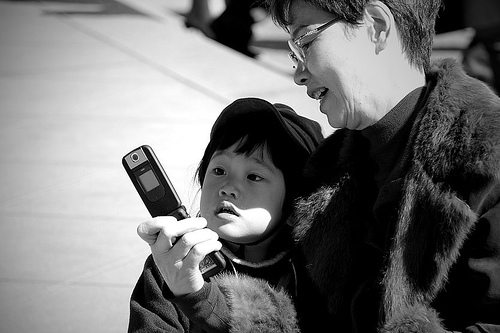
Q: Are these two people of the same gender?
A: Yes, all the people are female.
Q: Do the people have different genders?
A: No, all the people are female.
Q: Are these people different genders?
A: No, all the people are female.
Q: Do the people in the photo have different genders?
A: No, all the people are female.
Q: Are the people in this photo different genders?
A: No, all the people are female.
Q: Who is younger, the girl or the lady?
A: The girl is younger than the lady.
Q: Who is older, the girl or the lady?
A: The lady is older than the girl.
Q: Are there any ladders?
A: No, there are no ladders.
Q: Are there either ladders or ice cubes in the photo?
A: No, there are no ladders or ice cubes.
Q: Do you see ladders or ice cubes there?
A: No, there are no ladders or ice cubes.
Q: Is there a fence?
A: No, there are no fences.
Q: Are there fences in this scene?
A: No, there are no fences.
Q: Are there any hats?
A: Yes, there is a hat.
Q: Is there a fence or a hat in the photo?
A: Yes, there is a hat.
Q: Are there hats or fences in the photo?
A: Yes, there is a hat.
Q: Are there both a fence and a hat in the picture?
A: No, there is a hat but no fences.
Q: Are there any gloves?
A: No, there are no gloves.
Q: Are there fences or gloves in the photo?
A: No, there are no gloves or fences.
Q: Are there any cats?
A: No, there are no cats.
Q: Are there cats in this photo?
A: No, there are no cats.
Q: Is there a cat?
A: No, there are no cats.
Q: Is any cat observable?
A: No, there are no cats.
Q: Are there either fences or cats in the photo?
A: No, there are no cats or fences.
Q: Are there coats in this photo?
A: Yes, there is a coat.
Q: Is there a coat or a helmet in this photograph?
A: Yes, there is a coat.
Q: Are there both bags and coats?
A: No, there is a coat but no bags.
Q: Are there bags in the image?
A: No, there are no bags.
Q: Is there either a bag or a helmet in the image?
A: No, there are no bags or helmets.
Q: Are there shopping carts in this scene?
A: No, there are no shopping carts.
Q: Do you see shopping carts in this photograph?
A: No, there are no shopping carts.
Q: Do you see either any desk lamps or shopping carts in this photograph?
A: No, there are no shopping carts or desk lamps.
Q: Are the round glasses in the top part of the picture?
A: Yes, the glasses are in the top of the image.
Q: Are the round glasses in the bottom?
A: No, the glasses are in the top of the image.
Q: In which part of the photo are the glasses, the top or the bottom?
A: The glasses are in the top of the image.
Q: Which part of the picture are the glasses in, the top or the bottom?
A: The glasses are in the top of the image.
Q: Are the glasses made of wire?
A: Yes, the glasses are made of wire.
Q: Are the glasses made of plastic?
A: No, the glasses are made of wire.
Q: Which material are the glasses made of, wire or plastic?
A: The glasses are made of wire.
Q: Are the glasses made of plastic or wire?
A: The glasses are made of wire.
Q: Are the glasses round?
A: Yes, the glasses are round.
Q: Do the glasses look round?
A: Yes, the glasses are round.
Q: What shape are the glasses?
A: The glasses are round.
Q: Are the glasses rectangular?
A: No, the glasses are round.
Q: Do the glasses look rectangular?
A: No, the glasses are round.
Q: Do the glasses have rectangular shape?
A: No, the glasses are round.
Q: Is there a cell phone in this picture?
A: Yes, there is a cell phone.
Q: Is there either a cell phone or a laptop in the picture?
A: Yes, there is a cell phone.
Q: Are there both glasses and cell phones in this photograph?
A: Yes, there are both a cell phone and glasses.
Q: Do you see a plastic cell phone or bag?
A: Yes, there is a plastic cell phone.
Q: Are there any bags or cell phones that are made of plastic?
A: Yes, the cell phone is made of plastic.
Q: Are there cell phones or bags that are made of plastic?
A: Yes, the cell phone is made of plastic.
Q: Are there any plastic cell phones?
A: Yes, there is a cell phone that is made of plastic.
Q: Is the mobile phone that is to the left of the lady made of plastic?
A: Yes, the cell phone is made of plastic.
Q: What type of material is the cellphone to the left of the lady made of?
A: The mobile phone is made of plastic.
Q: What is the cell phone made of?
A: The mobile phone is made of plastic.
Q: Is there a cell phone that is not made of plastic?
A: No, there is a cell phone but it is made of plastic.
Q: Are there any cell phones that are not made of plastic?
A: No, there is a cell phone but it is made of plastic.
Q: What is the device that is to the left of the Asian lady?
A: The device is a cell phone.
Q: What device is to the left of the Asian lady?
A: The device is a cell phone.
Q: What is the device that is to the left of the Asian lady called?
A: The device is a cell phone.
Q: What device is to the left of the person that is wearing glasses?
A: The device is a cell phone.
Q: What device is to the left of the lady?
A: The device is a cell phone.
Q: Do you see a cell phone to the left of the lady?
A: Yes, there is a cell phone to the left of the lady.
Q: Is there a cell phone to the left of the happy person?
A: Yes, there is a cell phone to the left of the lady.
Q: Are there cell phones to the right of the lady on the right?
A: No, the cell phone is to the left of the lady.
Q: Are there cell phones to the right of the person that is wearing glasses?
A: No, the cell phone is to the left of the lady.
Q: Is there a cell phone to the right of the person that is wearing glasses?
A: No, the cell phone is to the left of the lady.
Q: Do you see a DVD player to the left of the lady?
A: No, there is a cell phone to the left of the lady.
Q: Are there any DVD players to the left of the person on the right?
A: No, there is a cell phone to the left of the lady.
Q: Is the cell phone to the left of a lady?
A: Yes, the cell phone is to the left of a lady.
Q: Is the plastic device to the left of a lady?
A: Yes, the cell phone is to the left of a lady.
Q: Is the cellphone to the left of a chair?
A: No, the cellphone is to the left of a lady.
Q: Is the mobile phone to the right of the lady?
A: No, the mobile phone is to the left of the lady.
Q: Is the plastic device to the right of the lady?
A: No, the mobile phone is to the left of the lady.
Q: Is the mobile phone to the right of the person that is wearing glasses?
A: No, the mobile phone is to the left of the lady.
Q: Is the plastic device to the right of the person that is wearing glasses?
A: No, the mobile phone is to the left of the lady.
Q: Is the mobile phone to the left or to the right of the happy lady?
A: The mobile phone is to the left of the lady.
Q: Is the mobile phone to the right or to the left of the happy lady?
A: The mobile phone is to the left of the lady.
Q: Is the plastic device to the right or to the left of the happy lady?
A: The mobile phone is to the left of the lady.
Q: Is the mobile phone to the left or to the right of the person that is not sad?
A: The mobile phone is to the left of the lady.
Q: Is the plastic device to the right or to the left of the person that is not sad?
A: The mobile phone is to the left of the lady.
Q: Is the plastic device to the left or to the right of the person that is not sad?
A: The mobile phone is to the left of the lady.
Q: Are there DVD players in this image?
A: No, there are no DVD players.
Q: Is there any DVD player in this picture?
A: No, there are no DVD players.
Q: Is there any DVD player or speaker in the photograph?
A: No, there are no DVD players or speakers.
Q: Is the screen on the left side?
A: Yes, the screen is on the left of the image.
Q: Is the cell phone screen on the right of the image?
A: No, the screen is on the left of the image.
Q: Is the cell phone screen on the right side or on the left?
A: The screen is on the left of the image.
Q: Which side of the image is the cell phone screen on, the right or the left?
A: The screen is on the left of the image.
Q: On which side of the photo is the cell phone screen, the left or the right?
A: The screen is on the left of the image.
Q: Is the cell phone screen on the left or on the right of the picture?
A: The screen is on the left of the image.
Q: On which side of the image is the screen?
A: The screen is on the left of the image.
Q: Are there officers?
A: No, there are no officers.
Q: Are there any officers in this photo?
A: No, there are no officers.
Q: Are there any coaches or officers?
A: No, there are no officers or coaches.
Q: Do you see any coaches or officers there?
A: No, there are no officers or coaches.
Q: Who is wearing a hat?
A: The girl is wearing a hat.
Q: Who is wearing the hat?
A: The girl is wearing a hat.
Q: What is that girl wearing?
A: The girl is wearing a hat.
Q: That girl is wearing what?
A: The girl is wearing a hat.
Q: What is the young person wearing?
A: The girl is wearing a hat.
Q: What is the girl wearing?
A: The girl is wearing a hat.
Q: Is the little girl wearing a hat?
A: Yes, the girl is wearing a hat.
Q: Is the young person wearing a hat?
A: Yes, the girl is wearing a hat.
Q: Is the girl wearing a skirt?
A: No, the girl is wearing a hat.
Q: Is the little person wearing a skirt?
A: No, the girl is wearing a hat.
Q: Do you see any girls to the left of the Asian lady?
A: Yes, there is a girl to the left of the lady.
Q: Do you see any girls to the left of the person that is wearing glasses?
A: Yes, there is a girl to the left of the lady.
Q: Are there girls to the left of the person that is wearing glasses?
A: Yes, there is a girl to the left of the lady.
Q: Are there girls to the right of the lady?
A: No, the girl is to the left of the lady.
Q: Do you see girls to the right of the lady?
A: No, the girl is to the left of the lady.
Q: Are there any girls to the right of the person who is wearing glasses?
A: No, the girl is to the left of the lady.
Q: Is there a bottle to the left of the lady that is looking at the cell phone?
A: No, there is a girl to the left of the lady.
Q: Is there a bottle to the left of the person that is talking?
A: No, there is a girl to the left of the lady.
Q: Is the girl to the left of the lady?
A: Yes, the girl is to the left of the lady.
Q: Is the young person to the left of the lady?
A: Yes, the girl is to the left of the lady.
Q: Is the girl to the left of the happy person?
A: Yes, the girl is to the left of the lady.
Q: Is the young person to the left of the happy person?
A: Yes, the girl is to the left of the lady.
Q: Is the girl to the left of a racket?
A: No, the girl is to the left of the lady.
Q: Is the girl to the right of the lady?
A: No, the girl is to the left of the lady.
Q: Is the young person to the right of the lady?
A: No, the girl is to the left of the lady.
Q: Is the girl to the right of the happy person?
A: No, the girl is to the left of the lady.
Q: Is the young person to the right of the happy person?
A: No, the girl is to the left of the lady.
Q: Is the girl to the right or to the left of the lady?
A: The girl is to the left of the lady.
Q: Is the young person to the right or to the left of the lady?
A: The girl is to the left of the lady.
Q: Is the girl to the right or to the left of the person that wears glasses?
A: The girl is to the left of the lady.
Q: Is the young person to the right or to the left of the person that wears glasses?
A: The girl is to the left of the lady.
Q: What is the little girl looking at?
A: The girl is looking at the cell phone.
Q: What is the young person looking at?
A: The girl is looking at the cell phone.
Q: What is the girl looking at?
A: The girl is looking at the cell phone.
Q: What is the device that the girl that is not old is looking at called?
A: The device is a cell phone.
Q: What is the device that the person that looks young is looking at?
A: The device is a cell phone.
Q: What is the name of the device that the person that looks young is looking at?
A: The device is a cell phone.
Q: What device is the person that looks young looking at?
A: The girl is looking at the cell phone.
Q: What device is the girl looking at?
A: The girl is looking at the cell phone.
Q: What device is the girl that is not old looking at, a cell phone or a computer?
A: The girl is looking at a cell phone.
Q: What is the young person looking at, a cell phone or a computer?
A: The girl is looking at a cell phone.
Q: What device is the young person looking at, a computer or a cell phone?
A: The girl is looking at a cell phone.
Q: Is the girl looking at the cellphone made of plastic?
A: Yes, the girl is looking at the cell phone.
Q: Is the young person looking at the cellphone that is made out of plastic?
A: Yes, the girl is looking at the cell phone.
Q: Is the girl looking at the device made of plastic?
A: Yes, the girl is looking at the cell phone.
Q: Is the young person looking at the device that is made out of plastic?
A: Yes, the girl is looking at the cell phone.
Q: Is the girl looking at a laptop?
A: No, the girl is looking at the cell phone.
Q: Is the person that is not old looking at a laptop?
A: No, the girl is looking at the cell phone.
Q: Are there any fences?
A: No, there are no fences.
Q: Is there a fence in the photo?
A: No, there are no fences.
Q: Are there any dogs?
A: No, there are no dogs.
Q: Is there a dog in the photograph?
A: No, there are no dogs.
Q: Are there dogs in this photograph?
A: No, there are no dogs.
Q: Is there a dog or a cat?
A: No, there are no dogs or cats.